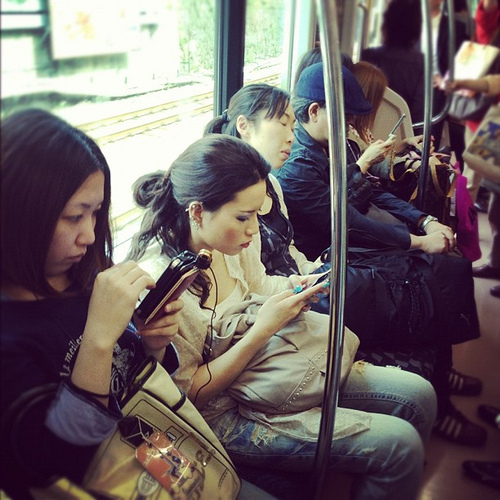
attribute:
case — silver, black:
[299, 267, 355, 300]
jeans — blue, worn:
[249, 320, 442, 498]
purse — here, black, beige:
[8, 378, 274, 494]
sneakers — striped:
[430, 393, 466, 432]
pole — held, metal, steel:
[298, 13, 360, 491]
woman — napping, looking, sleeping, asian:
[159, 112, 283, 496]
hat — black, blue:
[289, 59, 391, 113]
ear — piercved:
[183, 199, 206, 214]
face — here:
[216, 180, 289, 256]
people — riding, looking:
[23, 26, 457, 441]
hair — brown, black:
[8, 115, 77, 276]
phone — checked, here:
[301, 257, 346, 290]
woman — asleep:
[221, 78, 338, 187]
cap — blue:
[301, 63, 389, 146]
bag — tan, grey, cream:
[209, 294, 361, 411]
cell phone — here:
[143, 247, 230, 332]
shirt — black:
[1, 293, 125, 424]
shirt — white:
[138, 221, 267, 393]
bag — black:
[413, 154, 480, 230]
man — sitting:
[294, 82, 451, 367]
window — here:
[2, 24, 317, 141]